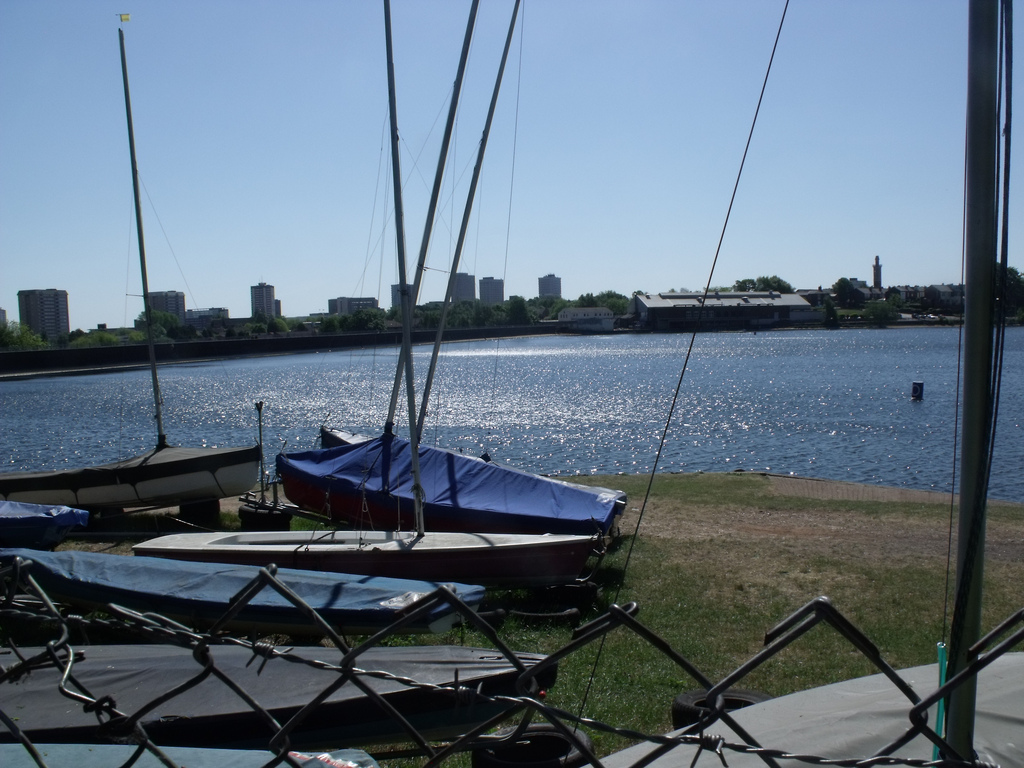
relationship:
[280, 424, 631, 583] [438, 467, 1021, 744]
boat on grass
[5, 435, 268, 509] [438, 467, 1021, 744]
boat on grass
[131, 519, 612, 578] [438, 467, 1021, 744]
boat on grass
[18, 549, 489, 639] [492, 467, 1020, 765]
boat on grass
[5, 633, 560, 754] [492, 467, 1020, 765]
boat on grass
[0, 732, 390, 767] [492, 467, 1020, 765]
boat on grass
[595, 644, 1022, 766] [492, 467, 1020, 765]
boat on grass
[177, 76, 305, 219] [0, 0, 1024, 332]
clouds in clouds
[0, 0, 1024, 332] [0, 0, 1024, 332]
clouds in clouds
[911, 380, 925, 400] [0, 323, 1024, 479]
buoy coming out of water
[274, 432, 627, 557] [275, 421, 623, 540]
boat on top of boat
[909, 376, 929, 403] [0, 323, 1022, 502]
buoy floating in water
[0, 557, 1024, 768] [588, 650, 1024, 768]
barbed wire on edge of all boat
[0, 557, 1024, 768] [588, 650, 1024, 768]
barbed wire in front of boat